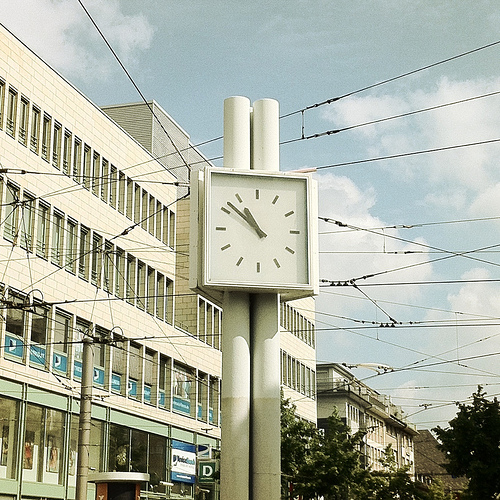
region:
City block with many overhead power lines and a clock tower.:
[5, 45, 497, 497]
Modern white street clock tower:
[184, 92, 321, 498]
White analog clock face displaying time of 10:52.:
[199, 166, 316, 289]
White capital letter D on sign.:
[194, 456, 218, 483]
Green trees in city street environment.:
[281, 385, 402, 497]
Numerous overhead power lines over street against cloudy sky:
[321, 53, 499, 432]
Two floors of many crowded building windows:
[1, 75, 174, 325]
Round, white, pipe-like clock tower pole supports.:
[216, 290, 286, 498]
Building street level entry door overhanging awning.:
[88, 466, 153, 496]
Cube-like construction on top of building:
[97, 101, 191, 185]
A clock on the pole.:
[173, 154, 317, 295]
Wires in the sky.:
[345, 264, 472, 387]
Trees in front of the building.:
[282, 391, 477, 498]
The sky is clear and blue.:
[181, 20, 443, 135]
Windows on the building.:
[26, 160, 176, 282]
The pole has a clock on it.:
[191, 278, 307, 481]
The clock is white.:
[154, 156, 339, 313]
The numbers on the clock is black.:
[223, 187, 286, 270]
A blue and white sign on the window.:
[151, 434, 208, 496]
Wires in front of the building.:
[15, 200, 155, 384]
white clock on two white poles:
[185, 98, 352, 330]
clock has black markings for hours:
[203, 176, 311, 283]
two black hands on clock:
[227, 195, 294, 282]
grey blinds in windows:
[16, 89, 80, 374]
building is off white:
[8, 61, 221, 497]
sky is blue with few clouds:
[250, 20, 487, 285]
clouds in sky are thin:
[318, 82, 493, 250]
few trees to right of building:
[285, 374, 498, 499]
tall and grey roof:
[113, 97, 218, 183]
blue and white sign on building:
[165, 441, 210, 492]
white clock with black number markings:
[190, 166, 317, 295]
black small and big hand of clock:
[217, 198, 274, 241]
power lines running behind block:
[34, 50, 495, 407]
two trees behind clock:
[266, 390, 499, 495]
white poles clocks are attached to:
[218, 96, 289, 494]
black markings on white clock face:
[211, 175, 301, 283]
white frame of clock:
[200, 163, 317, 294]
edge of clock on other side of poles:
[185, 166, 205, 292]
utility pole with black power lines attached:
[67, 341, 102, 498]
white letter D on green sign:
[190, 454, 219, 481]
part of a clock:
[249, 218, 287, 268]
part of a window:
[118, 393, 160, 450]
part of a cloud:
[436, 321, 461, 351]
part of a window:
[126, 417, 141, 425]